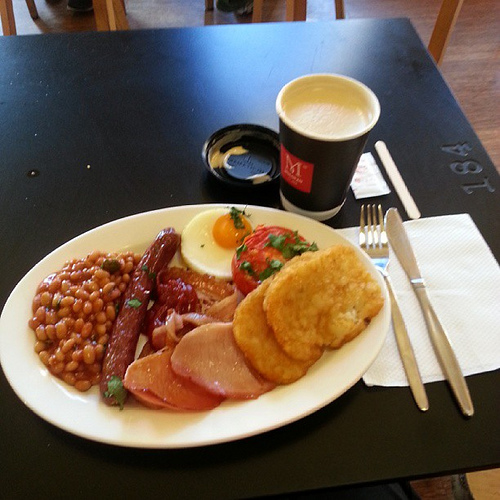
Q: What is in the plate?
A: Fodo.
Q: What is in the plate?
A: Food.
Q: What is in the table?
A: Fork.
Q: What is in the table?
A: Food.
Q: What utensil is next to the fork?
A: A knife.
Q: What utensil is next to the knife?
A: A fork.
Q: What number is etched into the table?
A: 184.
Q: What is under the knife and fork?
A: A white napkin.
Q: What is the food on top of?
A: A plate.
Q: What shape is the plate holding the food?
A: Oval.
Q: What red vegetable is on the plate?
A: Tomato.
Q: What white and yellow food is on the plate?
A: An egg.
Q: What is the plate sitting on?
A: A black table.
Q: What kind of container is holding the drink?
A: A cup.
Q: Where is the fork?
A: Left of the knife.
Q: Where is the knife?
A: Right of the fork.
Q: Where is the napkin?
A: Under the fork.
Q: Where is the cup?
A: By the plate.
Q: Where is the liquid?
A: In the cup.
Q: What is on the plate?
A: Breakfast.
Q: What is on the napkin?
A: Silverware.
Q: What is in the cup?
A: Coffee.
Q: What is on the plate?
A: Beans.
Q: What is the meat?
A: Sausage.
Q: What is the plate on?
A: A table.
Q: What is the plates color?
A: White plate.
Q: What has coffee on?
A: A lid.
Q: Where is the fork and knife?
A: On top of napkin.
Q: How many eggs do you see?
A: One.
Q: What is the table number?
A: 184.